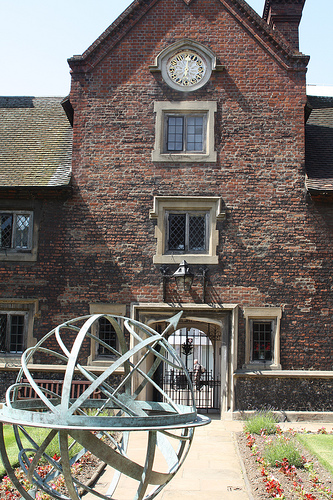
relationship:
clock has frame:
[172, 52, 204, 82] [144, 35, 228, 91]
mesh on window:
[163, 209, 209, 254] [153, 195, 220, 264]